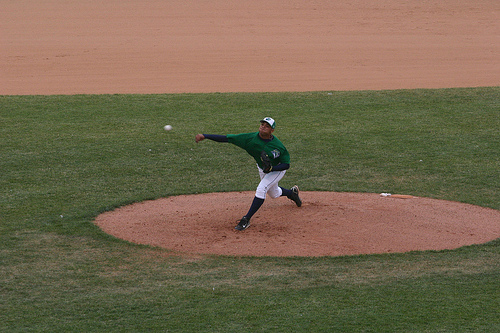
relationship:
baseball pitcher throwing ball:
[198, 119, 305, 232] [163, 122, 177, 135]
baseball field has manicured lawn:
[1, 2, 495, 330] [1, 85, 498, 332]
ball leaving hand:
[163, 122, 177, 135] [193, 132, 209, 145]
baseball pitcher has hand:
[198, 119, 305, 232] [193, 132, 209, 145]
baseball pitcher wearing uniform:
[198, 119, 305, 232] [208, 128, 294, 223]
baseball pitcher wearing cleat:
[198, 119, 305, 232] [237, 215, 251, 231]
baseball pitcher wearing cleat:
[198, 119, 305, 232] [291, 183, 303, 210]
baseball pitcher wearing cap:
[198, 119, 305, 232] [260, 115, 278, 131]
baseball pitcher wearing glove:
[198, 119, 305, 232] [259, 148, 283, 169]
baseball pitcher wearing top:
[198, 119, 305, 232] [226, 131, 291, 175]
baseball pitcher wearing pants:
[198, 119, 305, 232] [253, 162, 284, 201]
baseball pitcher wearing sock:
[198, 119, 305, 232] [243, 196, 264, 221]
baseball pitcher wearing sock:
[198, 119, 305, 232] [277, 184, 293, 202]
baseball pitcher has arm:
[198, 119, 305, 232] [197, 132, 253, 147]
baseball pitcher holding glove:
[198, 119, 305, 232] [259, 148, 283, 169]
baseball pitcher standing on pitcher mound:
[198, 119, 305, 232] [99, 182, 498, 260]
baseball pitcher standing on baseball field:
[198, 119, 305, 232] [1, 2, 495, 330]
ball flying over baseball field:
[163, 122, 177, 135] [1, 2, 495, 330]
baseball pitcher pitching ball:
[198, 119, 305, 232] [163, 122, 177, 135]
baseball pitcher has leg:
[198, 119, 305, 232] [239, 169, 285, 226]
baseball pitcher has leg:
[198, 119, 305, 232] [258, 161, 293, 205]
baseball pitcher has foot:
[198, 119, 305, 232] [236, 215, 252, 232]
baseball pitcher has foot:
[198, 119, 305, 232] [288, 184, 300, 206]